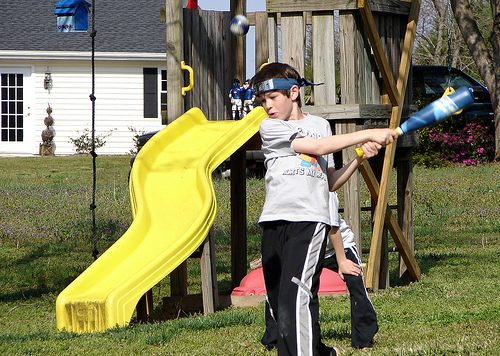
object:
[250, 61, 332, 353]
boy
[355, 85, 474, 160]
bat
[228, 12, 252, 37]
ball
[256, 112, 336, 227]
shirt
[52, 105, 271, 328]
slide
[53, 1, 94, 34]
birdhouse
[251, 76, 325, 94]
headband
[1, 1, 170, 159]
house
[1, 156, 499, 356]
grass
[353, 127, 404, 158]
handle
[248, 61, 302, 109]
dark hair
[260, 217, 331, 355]
pants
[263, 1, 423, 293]
fort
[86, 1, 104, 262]
rope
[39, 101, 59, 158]
tree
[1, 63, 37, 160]
door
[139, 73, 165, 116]
windows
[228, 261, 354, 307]
sandbox lid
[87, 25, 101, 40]
knot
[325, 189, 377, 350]
boy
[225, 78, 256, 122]
toys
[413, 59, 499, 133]
vehicle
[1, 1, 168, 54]
rooftop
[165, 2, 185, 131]
pole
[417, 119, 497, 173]
bush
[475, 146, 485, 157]
flower